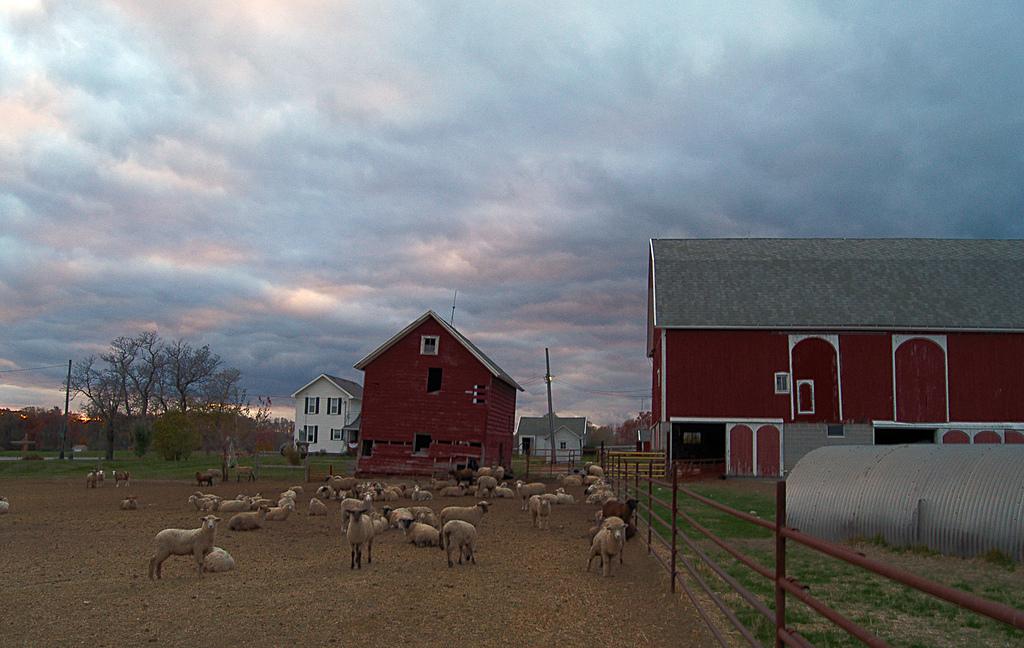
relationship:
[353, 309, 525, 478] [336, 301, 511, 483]
building on side of building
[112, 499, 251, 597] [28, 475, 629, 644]
sheep in grass field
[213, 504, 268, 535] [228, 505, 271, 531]
sheep with sheep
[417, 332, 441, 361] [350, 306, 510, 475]
window in a building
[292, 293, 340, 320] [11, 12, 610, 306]
portion of sky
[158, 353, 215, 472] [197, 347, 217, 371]
tree with leaves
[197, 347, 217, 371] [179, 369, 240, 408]
leaves in branches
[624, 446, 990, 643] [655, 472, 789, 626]
fence made of poles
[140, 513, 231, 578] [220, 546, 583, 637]
sheep looking towards side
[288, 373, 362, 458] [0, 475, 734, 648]
building in grass field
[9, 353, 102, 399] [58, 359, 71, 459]
wires connected to a wires